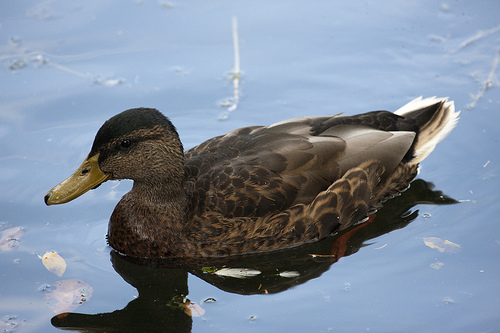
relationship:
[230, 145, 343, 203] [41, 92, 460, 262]
feather on duck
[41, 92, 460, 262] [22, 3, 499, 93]
duck in lake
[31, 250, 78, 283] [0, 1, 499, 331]
leaves on water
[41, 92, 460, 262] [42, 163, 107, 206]
duck has beak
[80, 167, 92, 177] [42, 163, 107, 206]
airway on beak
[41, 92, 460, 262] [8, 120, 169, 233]
duck has bill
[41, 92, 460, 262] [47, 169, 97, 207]
duck has peck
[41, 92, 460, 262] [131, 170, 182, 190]
duck has neck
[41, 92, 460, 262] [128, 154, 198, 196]
duck has neck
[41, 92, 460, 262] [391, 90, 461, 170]
duck has tail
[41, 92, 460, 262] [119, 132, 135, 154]
duck has eye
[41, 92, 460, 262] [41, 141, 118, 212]
duck has beak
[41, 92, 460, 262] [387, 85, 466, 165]
duck has tail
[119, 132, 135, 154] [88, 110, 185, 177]
eye on head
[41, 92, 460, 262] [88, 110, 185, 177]
duck has head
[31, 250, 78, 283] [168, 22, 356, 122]
leaves on water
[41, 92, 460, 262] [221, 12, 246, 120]
duck in branch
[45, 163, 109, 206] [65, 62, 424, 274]
beak of a duck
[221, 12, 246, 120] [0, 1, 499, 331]
branch floating in water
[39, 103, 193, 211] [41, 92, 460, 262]
head of duck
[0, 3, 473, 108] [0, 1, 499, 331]
ripples in water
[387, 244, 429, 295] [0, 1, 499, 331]
ripples in water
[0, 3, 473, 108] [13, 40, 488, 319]
ripples in water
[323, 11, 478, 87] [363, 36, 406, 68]
ripples in water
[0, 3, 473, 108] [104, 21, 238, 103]
ripples in water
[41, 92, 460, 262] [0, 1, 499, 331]
duck swimming in water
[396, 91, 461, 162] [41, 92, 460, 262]
tail of duck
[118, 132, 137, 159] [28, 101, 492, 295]
eye of duck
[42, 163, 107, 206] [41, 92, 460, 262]
beak of duck